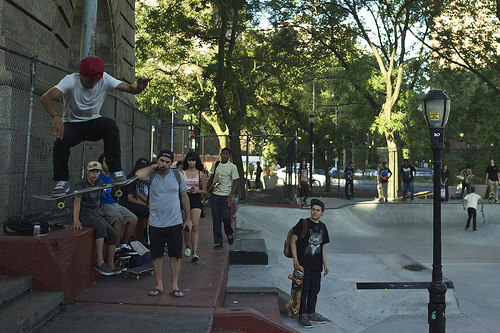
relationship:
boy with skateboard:
[32, 52, 159, 213] [32, 172, 141, 208]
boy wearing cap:
[32, 52, 159, 213] [72, 56, 113, 89]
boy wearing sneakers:
[32, 52, 159, 213] [43, 166, 135, 195]